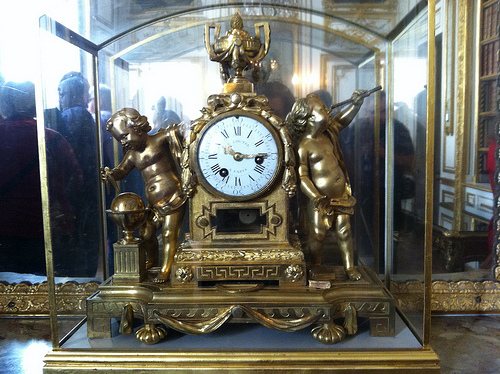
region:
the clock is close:
[87, 15, 393, 347]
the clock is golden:
[182, 90, 301, 294]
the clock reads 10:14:
[193, 111, 283, 200]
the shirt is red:
[0, 113, 74, 225]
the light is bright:
[125, 62, 207, 93]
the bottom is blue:
[81, 333, 128, 349]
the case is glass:
[376, 106, 427, 232]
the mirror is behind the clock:
[8, 7, 490, 303]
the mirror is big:
[6, 8, 498, 310]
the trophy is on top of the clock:
[207, 13, 272, 96]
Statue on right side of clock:
[289, 83, 377, 283]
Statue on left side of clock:
[88, 93, 193, 291]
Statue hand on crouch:
[301, 187, 345, 223]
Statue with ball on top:
[101, 184, 147, 286]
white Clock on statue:
[192, 103, 289, 208]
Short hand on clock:
[210, 134, 235, 159]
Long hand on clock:
[235, 153, 272, 162]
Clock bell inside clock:
[208, 207, 278, 232]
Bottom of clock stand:
[84, 283, 408, 349]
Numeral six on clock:
[230, 171, 242, 196]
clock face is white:
[190, 78, 283, 219]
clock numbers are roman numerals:
[185, 100, 260, 186]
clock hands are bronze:
[215, 125, 260, 165]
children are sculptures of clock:
[125, 80, 375, 280]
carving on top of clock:
[190, 25, 305, 85]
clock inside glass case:
[35, 25, 405, 330]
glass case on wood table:
[60, 0, 430, 360]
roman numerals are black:
[200, 125, 264, 182]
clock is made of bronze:
[116, 28, 376, 310]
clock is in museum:
[59, 21, 490, 368]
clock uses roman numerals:
[191, 101, 278, 206]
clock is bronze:
[115, 66, 390, 351]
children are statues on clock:
[80, 92, 362, 303]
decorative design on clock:
[160, 228, 298, 297]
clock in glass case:
[39, 16, 456, 339]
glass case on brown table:
[35, 1, 434, 361]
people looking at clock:
[28, 67, 115, 274]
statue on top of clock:
[205, 10, 287, 120]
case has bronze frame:
[380, 18, 455, 251]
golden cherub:
[86, 107, 190, 284]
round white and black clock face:
[196, 107, 287, 201]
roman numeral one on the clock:
[244, 129, 257, 139]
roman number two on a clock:
[251, 135, 266, 148]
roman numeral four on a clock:
[246, 173, 257, 182]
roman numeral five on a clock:
[231, 175, 243, 189]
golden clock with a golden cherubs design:
[91, 13, 406, 344]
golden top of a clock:
[201, 10, 275, 95]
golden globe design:
[103, 190, 152, 242]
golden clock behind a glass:
[35, 2, 438, 371]